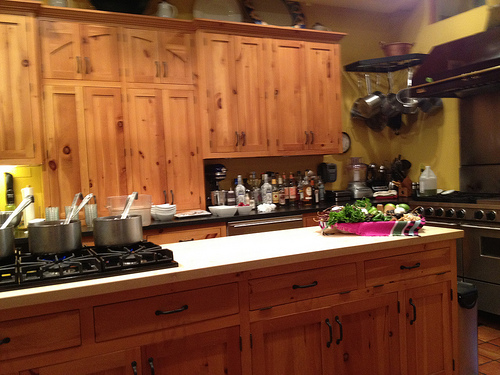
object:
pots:
[349, 87, 436, 135]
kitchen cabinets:
[252, 284, 399, 374]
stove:
[412, 185, 499, 224]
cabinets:
[2, 0, 42, 163]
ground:
[406, 124, 441, 166]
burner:
[0, 222, 13, 260]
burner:
[0, 240, 179, 294]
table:
[0, 202, 462, 310]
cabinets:
[20, 330, 148, 375]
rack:
[337, 40, 430, 75]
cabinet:
[245, 265, 361, 311]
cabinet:
[361, 245, 452, 288]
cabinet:
[93, 280, 239, 344]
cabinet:
[0, 308, 86, 360]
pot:
[93, 214, 144, 246]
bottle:
[236, 174, 247, 205]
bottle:
[261, 174, 272, 204]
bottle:
[271, 179, 278, 204]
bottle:
[302, 170, 313, 202]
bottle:
[289, 172, 296, 203]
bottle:
[282, 175, 288, 200]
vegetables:
[320, 197, 422, 229]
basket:
[318, 209, 424, 234]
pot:
[24, 218, 85, 254]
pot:
[0, 212, 15, 255]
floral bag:
[214, 163, 331, 207]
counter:
[0, 226, 464, 308]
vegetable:
[393, 207, 405, 217]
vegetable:
[360, 207, 367, 214]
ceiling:
[345, 0, 499, 76]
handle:
[155, 304, 186, 318]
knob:
[455, 208, 466, 216]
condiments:
[227, 172, 326, 205]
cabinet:
[124, 81, 168, 205]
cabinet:
[196, 27, 243, 156]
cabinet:
[265, 31, 309, 156]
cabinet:
[42, 76, 87, 223]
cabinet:
[124, 26, 191, 87]